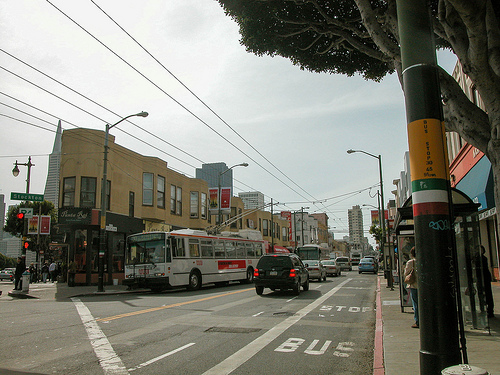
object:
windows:
[142, 171, 165, 210]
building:
[237, 190, 265, 211]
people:
[28, 260, 62, 284]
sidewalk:
[2, 272, 64, 286]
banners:
[207, 186, 234, 210]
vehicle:
[358, 257, 379, 274]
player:
[13, 255, 28, 291]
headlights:
[158, 272, 162, 276]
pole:
[95, 122, 109, 292]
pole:
[23, 156, 33, 210]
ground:
[0, 282, 379, 374]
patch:
[408, 115, 451, 180]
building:
[348, 205, 365, 252]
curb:
[370, 271, 387, 374]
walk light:
[25, 243, 31, 249]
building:
[57, 127, 291, 286]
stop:
[319, 304, 374, 314]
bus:
[124, 228, 269, 291]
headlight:
[156, 273, 164, 275]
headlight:
[125, 275, 129, 279]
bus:
[294, 243, 331, 260]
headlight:
[314, 263, 318, 266]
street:
[0, 254, 378, 374]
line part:
[282, 287, 337, 329]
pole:
[397, 0, 470, 375]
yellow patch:
[99, 215, 107, 229]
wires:
[0, 0, 382, 261]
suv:
[256, 251, 310, 296]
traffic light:
[17, 212, 26, 222]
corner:
[8, 283, 119, 298]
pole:
[214, 157, 225, 229]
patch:
[219, 187, 233, 218]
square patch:
[405, 118, 452, 183]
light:
[11, 155, 35, 292]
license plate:
[268, 267, 278, 277]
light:
[253, 269, 259, 276]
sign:
[9, 189, 46, 202]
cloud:
[159, 2, 214, 57]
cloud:
[229, 78, 404, 129]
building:
[196, 162, 233, 197]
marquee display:
[126, 233, 165, 244]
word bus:
[273, 335, 356, 359]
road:
[0, 265, 376, 375]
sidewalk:
[384, 290, 498, 373]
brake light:
[288, 268, 297, 278]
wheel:
[189, 267, 202, 290]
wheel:
[247, 266, 255, 285]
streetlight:
[347, 148, 356, 154]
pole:
[376, 152, 397, 291]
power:
[0, 0, 382, 247]